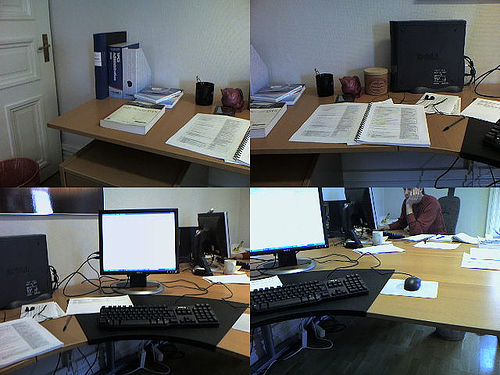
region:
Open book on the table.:
[291, 99, 434, 146]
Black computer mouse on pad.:
[403, 274, 421, 292]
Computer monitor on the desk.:
[96, 208, 178, 275]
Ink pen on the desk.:
[58, 313, 77, 334]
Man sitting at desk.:
[374, 187, 454, 243]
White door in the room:
[2, 0, 67, 185]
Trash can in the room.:
[3, 156, 43, 187]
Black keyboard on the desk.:
[96, 301, 219, 334]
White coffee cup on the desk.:
[221, 253, 239, 275]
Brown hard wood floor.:
[255, 308, 499, 372]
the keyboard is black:
[249, 270, 360, 318]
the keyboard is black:
[94, 289, 221, 342]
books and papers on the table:
[107, 84, 173, 146]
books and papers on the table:
[304, 92, 499, 154]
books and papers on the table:
[2, 292, 87, 372]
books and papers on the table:
[354, 225, 494, 273]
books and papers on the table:
[249, 235, 499, 296]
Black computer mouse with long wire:
[310, 249, 422, 291]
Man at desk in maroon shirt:
[376, 188, 446, 238]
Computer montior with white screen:
[95, 206, 181, 277]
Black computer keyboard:
[250, 270, 372, 315]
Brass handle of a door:
[38, 30, 52, 65]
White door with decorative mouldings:
[0, 0, 65, 180]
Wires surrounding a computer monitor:
[44, 248, 234, 301]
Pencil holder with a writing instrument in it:
[312, 66, 335, 101]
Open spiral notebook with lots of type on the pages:
[285, 98, 431, 149]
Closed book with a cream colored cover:
[95, 97, 167, 137]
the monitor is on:
[90, 193, 221, 313]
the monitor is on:
[245, 182, 335, 277]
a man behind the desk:
[374, 172, 464, 254]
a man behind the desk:
[387, 125, 455, 273]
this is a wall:
[170, 13, 201, 58]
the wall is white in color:
[165, 5, 216, 48]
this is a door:
[3, 3, 61, 108]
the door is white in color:
[17, 79, 42, 92]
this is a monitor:
[101, 209, 176, 288]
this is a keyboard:
[91, 298, 223, 325]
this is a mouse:
[391, 270, 426, 298]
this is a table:
[451, 273, 489, 325]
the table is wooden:
[451, 275, 486, 332]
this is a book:
[329, 108, 410, 142]